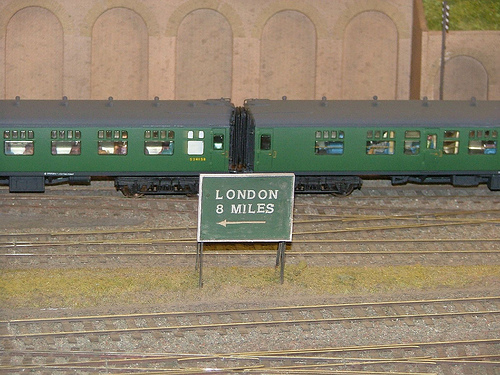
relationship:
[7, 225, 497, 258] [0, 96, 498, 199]
track for train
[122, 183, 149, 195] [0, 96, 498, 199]
wheel on train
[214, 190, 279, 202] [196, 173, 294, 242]
lettering on sign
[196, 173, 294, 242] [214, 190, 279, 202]
sign with lettering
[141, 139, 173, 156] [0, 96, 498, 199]
window on train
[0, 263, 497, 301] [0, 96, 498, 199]
grass by train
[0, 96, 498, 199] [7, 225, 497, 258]
train on track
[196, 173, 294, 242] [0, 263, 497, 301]
sign on grass